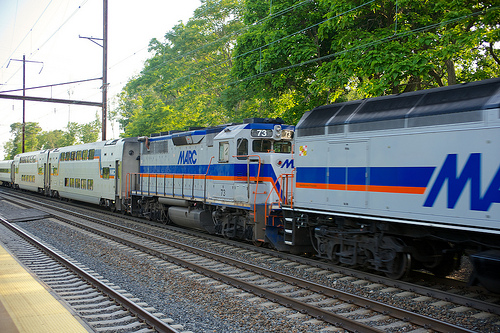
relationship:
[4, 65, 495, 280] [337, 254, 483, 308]
train on track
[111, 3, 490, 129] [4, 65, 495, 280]
trees next to train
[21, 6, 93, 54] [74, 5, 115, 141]
power lines between pole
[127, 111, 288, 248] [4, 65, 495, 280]
engine pulling train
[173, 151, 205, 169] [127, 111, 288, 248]
words on engine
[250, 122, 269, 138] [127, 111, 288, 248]
number on engine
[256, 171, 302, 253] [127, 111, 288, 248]
steps on engine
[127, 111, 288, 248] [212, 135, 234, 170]
engine has window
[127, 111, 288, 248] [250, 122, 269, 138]
engine has number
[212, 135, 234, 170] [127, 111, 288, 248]
window on engine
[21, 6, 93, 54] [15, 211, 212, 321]
power lines near track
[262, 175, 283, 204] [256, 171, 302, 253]
handle for steps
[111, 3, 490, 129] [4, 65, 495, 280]
trees near train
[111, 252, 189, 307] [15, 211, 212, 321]
gravel near track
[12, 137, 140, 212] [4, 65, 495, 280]
cars on train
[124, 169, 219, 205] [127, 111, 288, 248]
walkway on engine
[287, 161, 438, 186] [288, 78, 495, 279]
line on train car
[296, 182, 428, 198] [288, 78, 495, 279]
line on train car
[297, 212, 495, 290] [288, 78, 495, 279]
bottom of train car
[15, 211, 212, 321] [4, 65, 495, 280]
track next to train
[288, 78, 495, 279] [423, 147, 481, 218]
train car has letter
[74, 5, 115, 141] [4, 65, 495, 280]
pole next to train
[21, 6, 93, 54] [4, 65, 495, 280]
power lines are above train